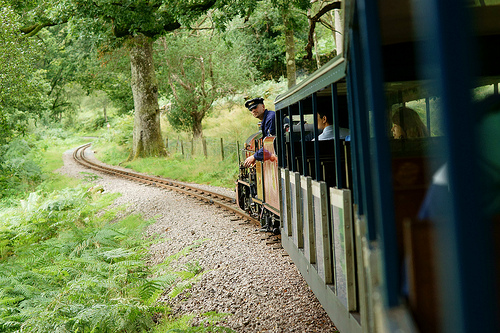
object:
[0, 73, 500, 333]
grass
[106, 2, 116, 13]
leaves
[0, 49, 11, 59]
leaves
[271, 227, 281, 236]
wheels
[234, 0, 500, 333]
train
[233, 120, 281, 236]
engine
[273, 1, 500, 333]
train cars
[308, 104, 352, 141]
man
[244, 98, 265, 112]
hat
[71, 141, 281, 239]
tracks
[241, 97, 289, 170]
conductor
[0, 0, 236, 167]
tree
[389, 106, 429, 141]
human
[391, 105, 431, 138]
hair